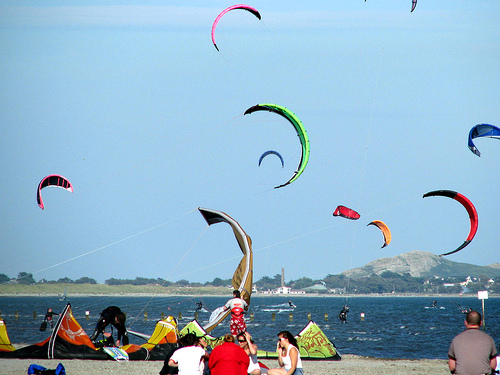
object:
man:
[90, 304, 135, 350]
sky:
[0, 0, 500, 284]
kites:
[238, 102, 310, 188]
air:
[0, 0, 499, 281]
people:
[263, 330, 305, 375]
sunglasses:
[276, 335, 284, 343]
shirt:
[170, 345, 208, 374]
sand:
[310, 359, 440, 375]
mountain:
[300, 250, 500, 297]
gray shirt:
[448, 327, 497, 375]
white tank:
[277, 344, 305, 369]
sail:
[330, 204, 360, 220]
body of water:
[0, 296, 500, 344]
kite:
[419, 191, 475, 258]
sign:
[476, 291, 490, 304]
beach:
[0, 359, 500, 375]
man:
[445, 311, 500, 374]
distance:
[0, 254, 499, 295]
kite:
[466, 124, 500, 156]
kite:
[209, 2, 264, 51]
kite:
[258, 149, 284, 170]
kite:
[34, 172, 70, 212]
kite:
[367, 220, 390, 248]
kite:
[294, 319, 338, 361]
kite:
[49, 303, 96, 358]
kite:
[193, 207, 257, 293]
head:
[276, 330, 292, 349]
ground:
[303, 356, 454, 375]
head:
[462, 309, 483, 327]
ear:
[461, 320, 468, 328]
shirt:
[205, 342, 252, 374]